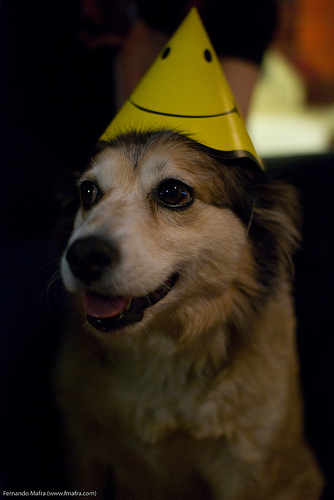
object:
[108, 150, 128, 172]
fur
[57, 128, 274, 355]
head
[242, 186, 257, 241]
band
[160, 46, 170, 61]
eye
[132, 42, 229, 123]
face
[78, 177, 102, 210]
eye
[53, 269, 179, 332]
mouth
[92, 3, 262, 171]
hat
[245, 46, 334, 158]
object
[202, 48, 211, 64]
spot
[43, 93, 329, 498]
dog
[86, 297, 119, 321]
tongue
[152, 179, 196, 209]
eye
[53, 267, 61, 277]
whiskers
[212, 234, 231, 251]
fur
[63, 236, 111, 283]
nose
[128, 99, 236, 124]
mouth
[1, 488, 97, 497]
watermark